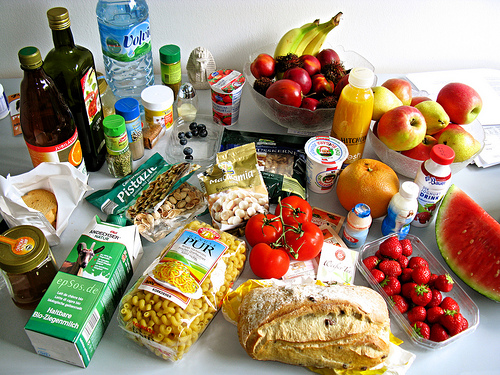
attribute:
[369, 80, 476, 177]
apples — green, red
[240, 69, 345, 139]
bowl — large, clear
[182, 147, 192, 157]
blueberry — small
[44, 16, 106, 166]
glass jar — tall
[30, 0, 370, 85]
white wall — painted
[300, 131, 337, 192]
yogurt container — white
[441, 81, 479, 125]
apple — large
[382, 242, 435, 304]
strawberries — clear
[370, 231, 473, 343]
container — rectangular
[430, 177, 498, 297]
watermelon piece — large, cut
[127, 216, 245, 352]
pasta bag — uncooked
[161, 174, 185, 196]
pistachio nuts — square-shaped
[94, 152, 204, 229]
bag — small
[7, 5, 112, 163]
bottles — dark, glass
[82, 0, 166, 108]
water bottle — clear, plastic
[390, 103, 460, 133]
apples — glass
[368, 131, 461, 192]
bowl — clear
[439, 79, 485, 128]
apple — red, sunlit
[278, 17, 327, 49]
bananas — yellow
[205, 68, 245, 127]
yogurt container — tall